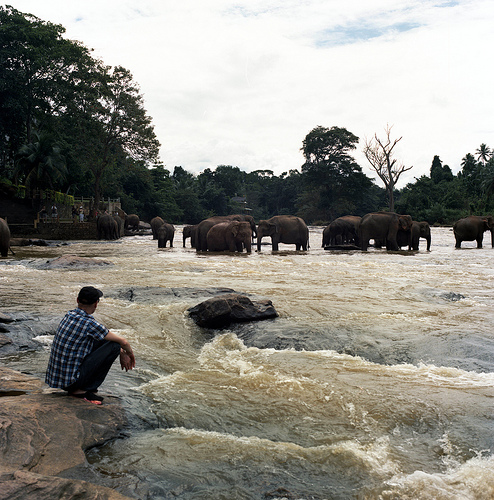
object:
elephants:
[453, 216, 494, 248]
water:
[0, 229, 494, 500]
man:
[47, 286, 135, 405]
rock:
[2, 372, 131, 499]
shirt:
[43, 307, 110, 387]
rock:
[184, 287, 278, 331]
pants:
[77, 341, 122, 397]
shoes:
[82, 390, 105, 404]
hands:
[117, 347, 136, 374]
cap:
[77, 285, 104, 303]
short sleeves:
[91, 318, 108, 346]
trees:
[300, 125, 369, 220]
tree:
[364, 128, 416, 212]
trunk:
[427, 235, 432, 253]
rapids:
[146, 290, 492, 499]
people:
[28, 199, 86, 229]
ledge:
[13, 222, 128, 240]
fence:
[74, 192, 128, 218]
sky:
[0, 0, 494, 152]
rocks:
[1, 232, 66, 389]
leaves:
[0, 0, 160, 183]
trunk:
[256, 232, 263, 252]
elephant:
[257, 215, 310, 254]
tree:
[19, 129, 77, 221]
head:
[229, 221, 253, 255]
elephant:
[206, 220, 253, 257]